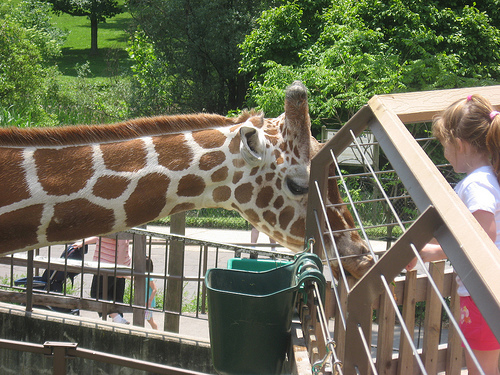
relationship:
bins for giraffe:
[205, 253, 324, 374] [1, 80, 378, 281]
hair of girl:
[425, 74, 499, 146] [431, 94, 498, 374]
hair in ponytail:
[425, 74, 499, 146] [487, 113, 497, 168]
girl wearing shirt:
[71, 234, 134, 326] [91, 234, 130, 273]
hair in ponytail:
[425, 94, 498, 182] [467, 95, 499, 180]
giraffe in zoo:
[1, 109, 373, 263] [0, 82, 499, 372]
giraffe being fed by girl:
[1, 80, 378, 281] [409, 113, 497, 248]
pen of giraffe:
[1, 84, 498, 374] [1, 80, 378, 281]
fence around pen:
[0, 207, 301, 339] [1, 84, 498, 374]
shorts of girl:
[453, 294, 499, 354] [431, 94, 498, 374]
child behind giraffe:
[115, 256, 158, 330] [1, 80, 378, 281]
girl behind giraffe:
[71, 234, 134, 326] [1, 80, 378, 281]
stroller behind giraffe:
[14, 240, 84, 314] [1, 80, 378, 281]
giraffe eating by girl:
[1, 80, 378, 281] [431, 94, 498, 374]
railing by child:
[310, 83, 498, 354] [405, 94, 500, 375]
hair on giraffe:
[1, 111, 235, 147] [1, 80, 378, 281]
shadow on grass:
[67, 50, 115, 65] [68, 20, 89, 47]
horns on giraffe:
[279, 76, 320, 141] [1, 80, 378, 281]